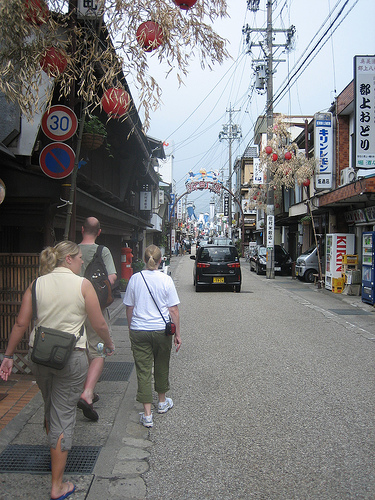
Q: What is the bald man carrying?
A: A backpack.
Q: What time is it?
A: Afternoon.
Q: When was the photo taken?
A: During the daytime.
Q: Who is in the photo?
A: Some people.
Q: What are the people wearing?
A: Clothing.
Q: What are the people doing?
A: Walking.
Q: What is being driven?
A: A car.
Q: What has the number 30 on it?
A: The sign.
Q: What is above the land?
A: The sky.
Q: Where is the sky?
A: Above the land.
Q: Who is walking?
A: The people.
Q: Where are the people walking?
A: Sidewalk.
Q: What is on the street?
A: Cars.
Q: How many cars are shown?
A: Three.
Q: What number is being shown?
A: Thirty.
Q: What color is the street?
A: Grey.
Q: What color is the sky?
A: Blue.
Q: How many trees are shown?
A: Two.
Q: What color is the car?
A: Black.